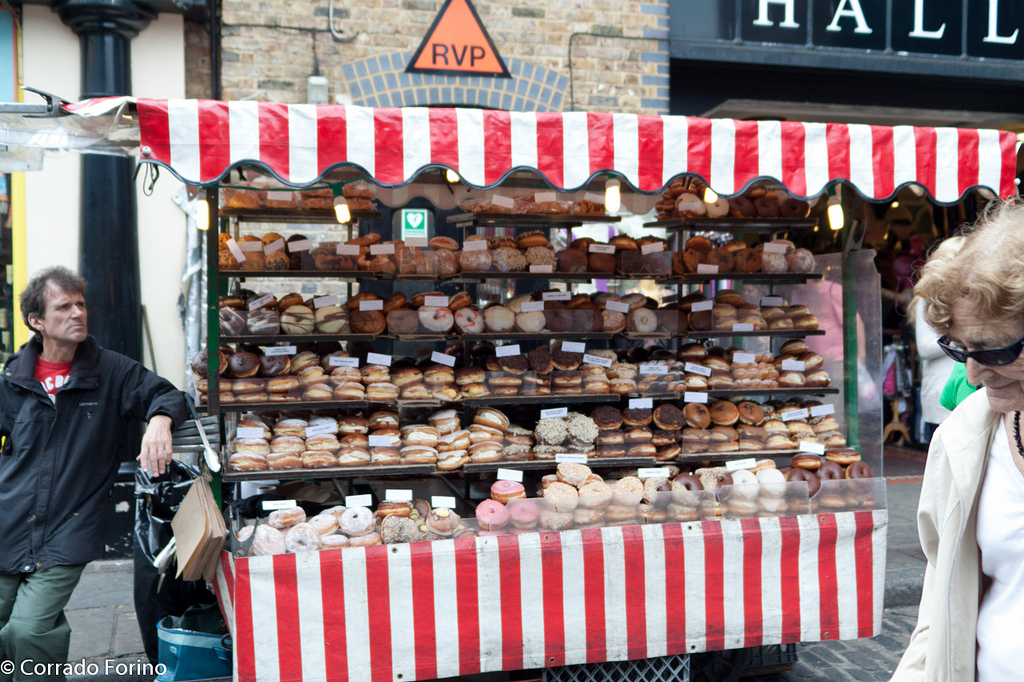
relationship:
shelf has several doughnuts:
[291, 392, 616, 418] [458, 463, 819, 500]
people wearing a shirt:
[892, 199, 1024, 682] [985, 512, 992, 573]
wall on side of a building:
[235, 37, 303, 96] [222, 1, 990, 105]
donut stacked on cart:
[486, 482, 539, 521] [220, 534, 866, 651]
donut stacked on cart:
[764, 444, 879, 509] [146, 474, 879, 676]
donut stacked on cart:
[548, 459, 605, 505] [214, 536, 899, 664]